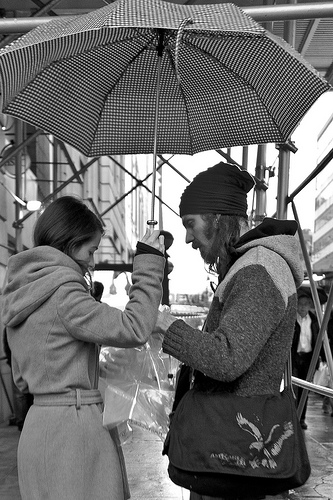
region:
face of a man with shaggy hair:
[180, 210, 250, 265]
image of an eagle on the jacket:
[209, 414, 296, 470]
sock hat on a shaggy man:
[178, 160, 256, 216]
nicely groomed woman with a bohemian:
[0, 196, 164, 499]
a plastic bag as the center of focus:
[100, 330, 192, 440]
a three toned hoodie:
[163, 217, 303, 391]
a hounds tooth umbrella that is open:
[0, 0, 332, 155]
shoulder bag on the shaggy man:
[163, 393, 310, 495]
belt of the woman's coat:
[31, 388, 102, 408]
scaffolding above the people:
[0, 83, 330, 412]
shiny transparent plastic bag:
[99, 323, 177, 440]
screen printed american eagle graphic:
[207, 410, 294, 472]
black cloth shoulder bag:
[153, 386, 316, 495]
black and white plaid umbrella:
[1, 0, 326, 160]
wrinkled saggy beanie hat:
[174, 159, 254, 222]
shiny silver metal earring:
[211, 214, 222, 224]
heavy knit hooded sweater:
[156, 217, 309, 402]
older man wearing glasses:
[284, 291, 323, 437]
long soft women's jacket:
[0, 242, 166, 498]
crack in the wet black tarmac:
[311, 465, 332, 498]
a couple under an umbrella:
[2, 1, 329, 497]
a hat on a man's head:
[176, 159, 258, 218]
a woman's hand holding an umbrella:
[127, 213, 174, 288]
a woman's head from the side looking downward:
[5, 172, 112, 315]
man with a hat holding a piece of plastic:
[93, 157, 308, 498]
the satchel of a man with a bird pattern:
[156, 372, 319, 494]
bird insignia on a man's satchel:
[205, 408, 295, 477]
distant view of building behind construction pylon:
[11, 149, 179, 196]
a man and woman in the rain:
[12, 0, 302, 490]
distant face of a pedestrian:
[294, 291, 325, 431]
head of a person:
[166, 137, 254, 268]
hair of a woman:
[20, 186, 107, 284]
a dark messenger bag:
[141, 356, 325, 493]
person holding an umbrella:
[12, 0, 327, 217]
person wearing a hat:
[170, 161, 264, 279]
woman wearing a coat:
[10, 188, 147, 498]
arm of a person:
[155, 305, 249, 388]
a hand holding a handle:
[120, 212, 177, 264]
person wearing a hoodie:
[137, 165, 317, 492]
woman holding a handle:
[1, 189, 183, 498]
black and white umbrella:
[4, 1, 299, 148]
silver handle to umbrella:
[147, 45, 161, 227]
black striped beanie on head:
[182, 169, 255, 217]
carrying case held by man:
[161, 380, 298, 492]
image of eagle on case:
[217, 405, 302, 473]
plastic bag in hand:
[112, 339, 159, 436]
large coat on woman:
[0, 262, 121, 492]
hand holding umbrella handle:
[128, 215, 165, 273]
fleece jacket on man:
[152, 225, 298, 393]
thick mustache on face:
[189, 238, 197, 252]